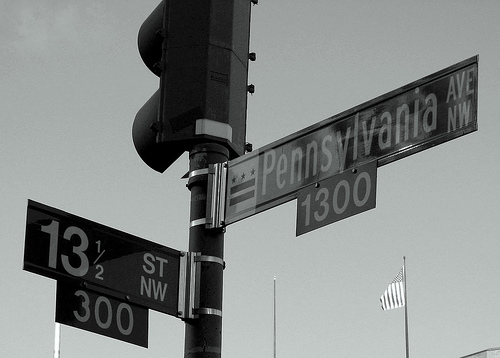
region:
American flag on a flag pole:
[372, 257, 414, 327]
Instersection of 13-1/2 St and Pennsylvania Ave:
[26, 67, 498, 343]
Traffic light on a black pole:
[115, 2, 264, 356]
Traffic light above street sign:
[132, 19, 464, 224]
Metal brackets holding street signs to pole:
[175, 159, 248, 338]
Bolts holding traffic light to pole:
[238, 1, 270, 156]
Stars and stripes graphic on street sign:
[215, 147, 273, 229]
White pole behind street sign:
[47, 314, 66, 356]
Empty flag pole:
[257, 276, 286, 356]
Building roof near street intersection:
[429, 336, 499, 356]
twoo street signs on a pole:
[27, 22, 499, 274]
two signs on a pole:
[27, 35, 464, 355]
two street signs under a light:
[19, 17, 495, 323]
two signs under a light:
[9, 9, 426, 352]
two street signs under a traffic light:
[30, 36, 499, 353]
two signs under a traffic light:
[30, 23, 385, 346]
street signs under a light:
[18, 11, 492, 355]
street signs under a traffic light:
[41, 31, 499, 353]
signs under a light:
[39, 31, 407, 336]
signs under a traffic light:
[65, 25, 493, 325]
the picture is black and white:
[2, 0, 497, 356]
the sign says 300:
[68, 287, 144, 343]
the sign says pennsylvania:
[256, 80, 441, 191]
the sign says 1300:
[298, 170, 382, 236]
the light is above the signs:
[127, 0, 260, 174]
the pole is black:
[181, 139, 228, 356]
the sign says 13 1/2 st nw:
[36, 211, 173, 313]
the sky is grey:
[1, 0, 498, 357]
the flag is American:
[370, 262, 412, 315]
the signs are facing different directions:
[18, 50, 482, 350]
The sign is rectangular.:
[201, 56, 495, 235]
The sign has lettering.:
[190, 52, 490, 230]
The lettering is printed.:
[188, 56, 483, 238]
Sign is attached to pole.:
[177, 1, 489, 356]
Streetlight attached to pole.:
[129, 2, 254, 356]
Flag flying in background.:
[368, 237, 424, 356]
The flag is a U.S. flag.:
[368, 244, 430, 356]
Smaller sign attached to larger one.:
[198, 53, 483, 248]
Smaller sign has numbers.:
[198, 55, 485, 257]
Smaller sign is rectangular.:
[187, 52, 494, 254]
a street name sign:
[220, 65, 481, 229]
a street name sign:
[27, 199, 182, 313]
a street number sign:
[50, 278, 154, 347]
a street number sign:
[289, 173, 375, 230]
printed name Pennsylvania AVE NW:
[248, 55, 488, 205]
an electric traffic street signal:
[132, 0, 251, 175]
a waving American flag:
[377, 253, 408, 356]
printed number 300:
[63, 286, 135, 338]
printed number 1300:
[295, 170, 375, 227]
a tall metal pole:
[266, 272, 281, 356]